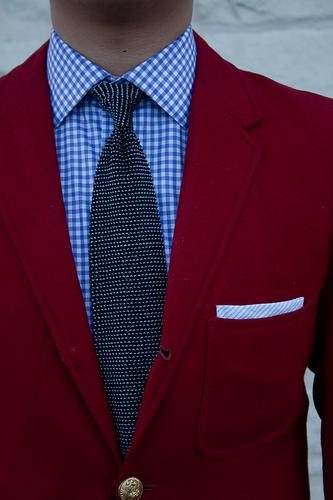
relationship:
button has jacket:
[111, 436, 158, 498] [0, 29, 331, 497]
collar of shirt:
[44, 25, 196, 128] [45, 21, 196, 337]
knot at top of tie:
[94, 85, 144, 132] [86, 76, 174, 457]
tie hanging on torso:
[86, 76, 174, 457] [0, 184, 308, 419]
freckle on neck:
[122, 49, 125, 52] [49, 0, 193, 76]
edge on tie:
[148, 176, 157, 195] [86, 76, 174, 457]